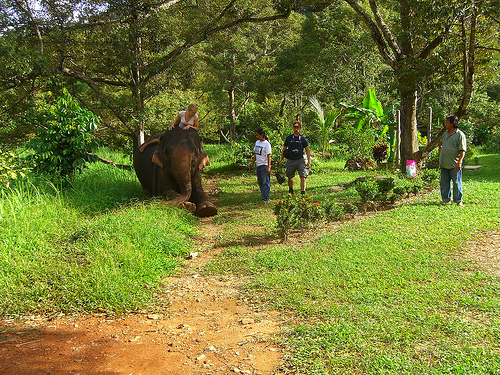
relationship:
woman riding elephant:
[139, 106, 202, 159] [131, 124, 223, 221]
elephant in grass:
[131, 124, 223, 221] [0, 141, 500, 375]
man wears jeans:
[436, 114, 471, 209] [438, 164, 465, 204]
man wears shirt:
[436, 114, 471, 209] [435, 127, 470, 171]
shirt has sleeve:
[435, 127, 470, 171] [436, 130, 450, 144]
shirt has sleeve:
[435, 127, 470, 171] [455, 132, 470, 154]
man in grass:
[436, 114, 471, 209] [0, 141, 500, 375]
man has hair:
[436, 114, 471, 209] [444, 114, 460, 133]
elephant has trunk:
[131, 124, 223, 221] [159, 155, 195, 210]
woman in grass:
[244, 126, 277, 205] [0, 141, 500, 375]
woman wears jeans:
[244, 126, 277, 205] [255, 164, 273, 201]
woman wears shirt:
[244, 126, 277, 205] [250, 139, 274, 170]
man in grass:
[277, 119, 315, 202] [0, 141, 500, 375]